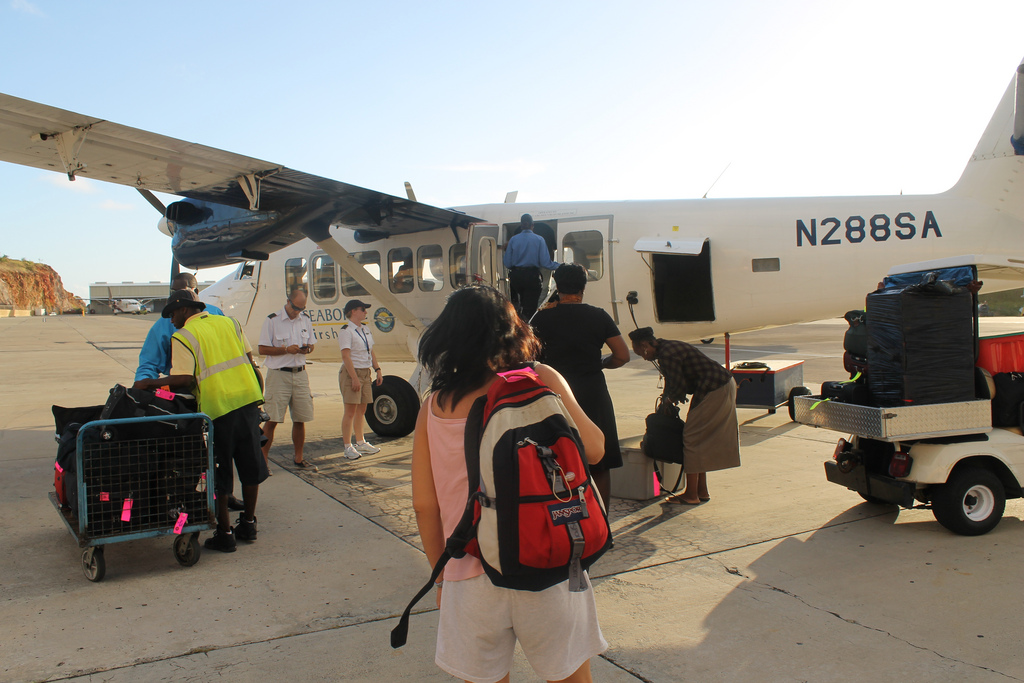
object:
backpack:
[391, 360, 615, 650]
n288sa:
[796, 210, 943, 247]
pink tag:
[173, 512, 189, 534]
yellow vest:
[170, 311, 266, 424]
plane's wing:
[0, 94, 488, 269]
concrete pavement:
[0, 313, 80, 679]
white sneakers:
[343, 442, 379, 460]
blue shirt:
[504, 229, 561, 270]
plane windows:
[388, 247, 415, 294]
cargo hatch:
[632, 237, 728, 324]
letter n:
[797, 219, 816, 247]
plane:
[0, 60, 1024, 437]